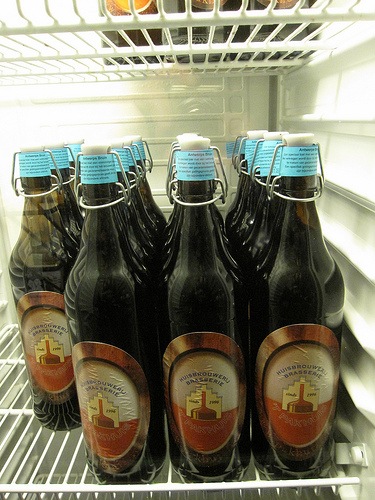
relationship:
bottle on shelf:
[250, 132, 345, 478] [1, 322, 359, 493]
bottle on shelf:
[158, 137, 250, 483] [1, 322, 359, 493]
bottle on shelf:
[62, 144, 163, 484] [1, 322, 359, 493]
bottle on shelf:
[11, 148, 80, 431] [1, 322, 359, 493]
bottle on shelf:
[39, 137, 81, 239] [1, 322, 359, 493]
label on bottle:
[249, 316, 341, 452] [244, 154, 358, 474]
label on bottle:
[158, 326, 251, 460] [152, 129, 254, 482]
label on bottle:
[71, 340, 151, 477] [62, 144, 163, 484]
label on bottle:
[17, 288, 76, 395] [11, 148, 80, 431]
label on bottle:
[15, 290, 75, 405] [11, 148, 80, 431]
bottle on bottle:
[64, 144, 167, 484] [62, 144, 163, 484]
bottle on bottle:
[62, 144, 163, 484] [152, 129, 254, 482]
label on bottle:
[254, 324, 340, 462] [245, 132, 345, 480]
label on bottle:
[68, 339, 156, 478] [55, 137, 170, 488]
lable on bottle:
[252, 134, 328, 185] [234, 118, 352, 492]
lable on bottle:
[280, 146, 319, 178] [255, 140, 339, 316]